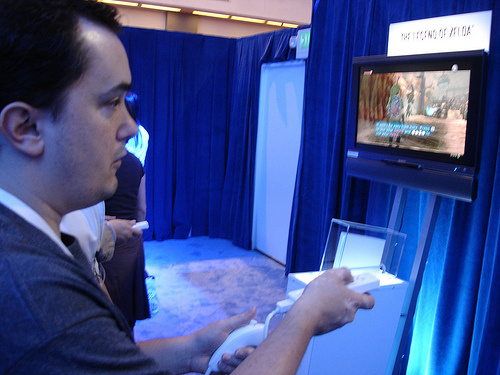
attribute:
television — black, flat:
[344, 48, 491, 203]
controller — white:
[272, 270, 380, 317]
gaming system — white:
[275, 261, 407, 373]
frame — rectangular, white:
[249, 55, 309, 269]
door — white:
[249, 58, 307, 264]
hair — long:
[122, 91, 143, 150]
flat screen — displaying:
[335, 38, 479, 171]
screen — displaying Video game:
[352, 57, 476, 157]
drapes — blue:
[77, 23, 311, 283]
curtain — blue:
[172, 47, 283, 232]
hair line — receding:
[59, 16, 101, 66]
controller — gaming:
[211, 257, 401, 357]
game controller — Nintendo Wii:
[289, 272, 380, 323]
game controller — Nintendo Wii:
[202, 309, 266, 374]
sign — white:
[388, 14, 498, 61]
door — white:
[250, 57, 312, 268]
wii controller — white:
[273, 272, 379, 319]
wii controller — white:
[205, 317, 271, 372]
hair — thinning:
[9, 2, 129, 140]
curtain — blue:
[285, 0, 496, 371]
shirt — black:
[4, 191, 243, 371]